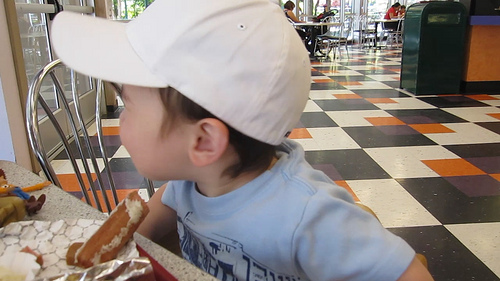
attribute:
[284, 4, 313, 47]
woman — Feeding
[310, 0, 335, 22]
baby — Fed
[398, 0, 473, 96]
trashcan — Metal, Green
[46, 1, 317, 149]
cap — White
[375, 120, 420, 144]
tile — Purple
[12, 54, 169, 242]
chair — shiny, grey, metal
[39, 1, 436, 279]
person — Seated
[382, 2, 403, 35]
woman — Seated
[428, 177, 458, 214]
tile — Black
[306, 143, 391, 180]
tile — Black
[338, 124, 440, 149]
black tile — Black 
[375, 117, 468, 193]
tile — Black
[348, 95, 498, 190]
tiled floor — White, Purple, Orange, Black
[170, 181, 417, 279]
shirt — light, blue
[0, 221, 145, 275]
food — Served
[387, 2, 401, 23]
people — Seated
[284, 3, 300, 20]
people — Seated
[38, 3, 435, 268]
people — Seated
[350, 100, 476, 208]
tile — Orange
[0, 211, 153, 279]
wrapper — Aluminum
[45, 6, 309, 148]
hat — white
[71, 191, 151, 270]
hotdog — half-eaten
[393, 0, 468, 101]
trashcan — green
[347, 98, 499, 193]
floor — checkered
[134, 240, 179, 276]
tray — red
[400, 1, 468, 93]
trash can — green, metal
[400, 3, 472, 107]
trashcan — metal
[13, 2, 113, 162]
doors — Silver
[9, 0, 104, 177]
door — metal, glass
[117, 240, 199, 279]
tray — Red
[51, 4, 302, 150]
baseball cap — white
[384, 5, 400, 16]
shirt — Red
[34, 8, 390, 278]
boy — Seated